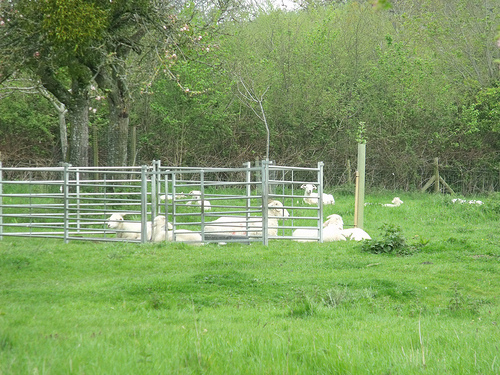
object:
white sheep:
[106, 212, 152, 241]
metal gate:
[157, 157, 268, 245]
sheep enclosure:
[1, 155, 500, 374]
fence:
[0, 160, 324, 245]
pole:
[139, 162, 151, 245]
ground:
[0, 190, 500, 374]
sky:
[171, 0, 307, 22]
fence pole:
[352, 139, 370, 240]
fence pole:
[265, 205, 323, 211]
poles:
[432, 155, 442, 195]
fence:
[322, 164, 500, 195]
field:
[0, 188, 498, 374]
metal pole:
[355, 143, 365, 234]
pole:
[265, 227, 320, 231]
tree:
[232, 75, 277, 194]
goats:
[299, 182, 337, 207]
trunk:
[40, 67, 95, 202]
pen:
[0, 157, 329, 247]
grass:
[0, 184, 500, 375]